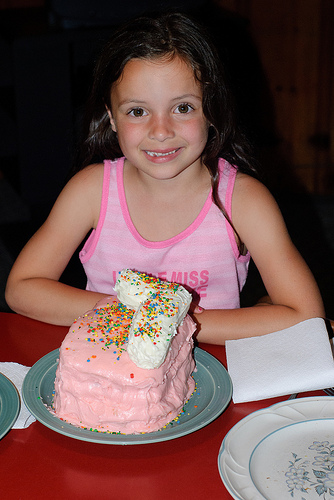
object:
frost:
[51, 270, 195, 432]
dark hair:
[83, 11, 261, 181]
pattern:
[285, 439, 332, 500]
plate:
[21, 341, 233, 445]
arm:
[4, 164, 116, 328]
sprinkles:
[92, 304, 128, 349]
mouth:
[139, 146, 186, 164]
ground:
[255, 109, 278, 131]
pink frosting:
[52, 294, 196, 434]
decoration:
[284, 433, 333, 498]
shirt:
[79, 156, 251, 310]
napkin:
[225, 317, 333, 405]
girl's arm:
[194, 174, 326, 345]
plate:
[218, 395, 333, 498]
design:
[286, 433, 334, 499]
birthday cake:
[51, 265, 198, 435]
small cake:
[113, 268, 192, 370]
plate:
[0, 370, 21, 438]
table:
[0, 313, 333, 498]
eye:
[123, 104, 152, 117]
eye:
[173, 101, 196, 115]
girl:
[4, 15, 326, 344]